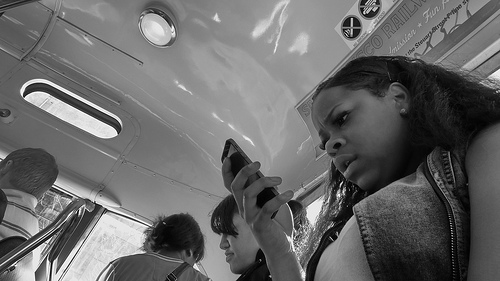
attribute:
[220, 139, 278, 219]
phone — cell